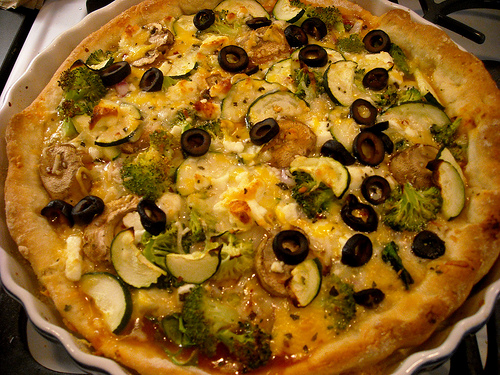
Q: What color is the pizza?
A: Yellow, black, and green.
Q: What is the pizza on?
A: A dish.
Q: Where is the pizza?
A: In a dish.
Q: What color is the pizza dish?
A: White.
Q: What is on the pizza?
A: Olives, zucchini, and broccoli.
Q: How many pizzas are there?
A: One.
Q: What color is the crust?
A: Brown.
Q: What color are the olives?
A: Black.